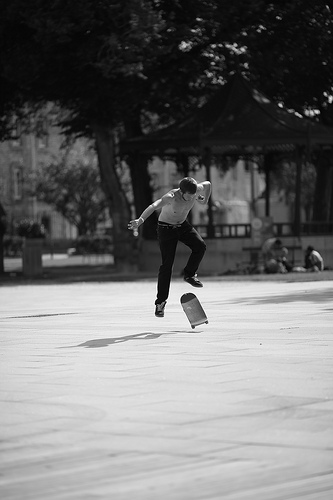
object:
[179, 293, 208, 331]
board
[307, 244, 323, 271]
guys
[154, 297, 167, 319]
shoe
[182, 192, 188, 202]
beard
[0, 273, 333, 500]
pavement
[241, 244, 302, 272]
bench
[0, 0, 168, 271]
trees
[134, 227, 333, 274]
wall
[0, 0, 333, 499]
park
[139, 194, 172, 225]
arm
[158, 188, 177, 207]
shoulder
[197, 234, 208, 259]
knee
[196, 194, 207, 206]
hand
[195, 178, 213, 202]
arm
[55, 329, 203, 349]
shadow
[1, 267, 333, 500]
ground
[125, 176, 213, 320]
guy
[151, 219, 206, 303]
pants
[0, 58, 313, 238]
building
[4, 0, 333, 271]
background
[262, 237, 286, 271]
people